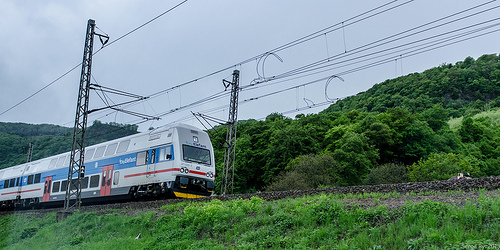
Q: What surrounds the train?
A: Trees.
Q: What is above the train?
A: Wires.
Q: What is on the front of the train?
A: A window.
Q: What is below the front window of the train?
A: Headlights.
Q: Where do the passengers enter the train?
A: The doors.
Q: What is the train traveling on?
A: Train tracks.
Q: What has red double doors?
A: The train.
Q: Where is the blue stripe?
A: On the side of the train.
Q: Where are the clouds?
A: In the sky.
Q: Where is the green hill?
A: In front of the train.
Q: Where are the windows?
A: On the side of the train.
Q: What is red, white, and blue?
A: The train.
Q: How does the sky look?
A: Overcast.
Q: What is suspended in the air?
A: Wires.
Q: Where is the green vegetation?
A: On the hill.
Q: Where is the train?
A: On the tracks.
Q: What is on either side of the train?
A: Two metal towers for wires.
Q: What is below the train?
A: A grassy hill.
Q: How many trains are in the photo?
A: One.